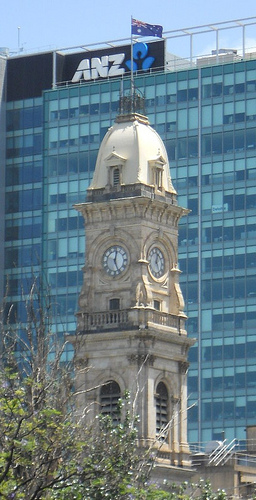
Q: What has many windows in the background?
A: A building.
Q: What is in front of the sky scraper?
A: A clock tower.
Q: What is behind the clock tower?
A: A sky scraper.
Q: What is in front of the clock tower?
A: A tree.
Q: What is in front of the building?
A: A clock tower.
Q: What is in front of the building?
A: A brown building.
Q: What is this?
A: A clock tower.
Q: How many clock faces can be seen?
A: Two.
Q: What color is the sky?
A: Light blue.